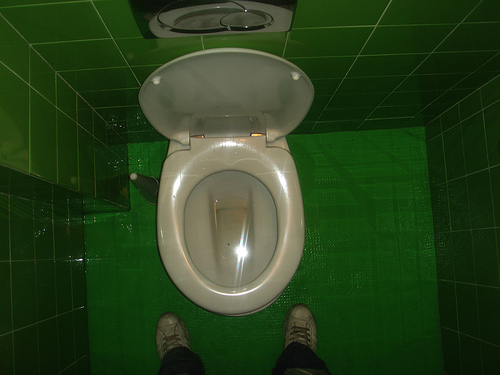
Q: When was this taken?
A: During the day.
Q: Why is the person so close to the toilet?
A: About to use it.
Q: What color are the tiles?
A: Green.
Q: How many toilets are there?
A: One.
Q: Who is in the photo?
A: 1 person.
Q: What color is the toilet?
A: White.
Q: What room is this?
A: Bathroom.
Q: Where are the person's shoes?
A: On the floor.